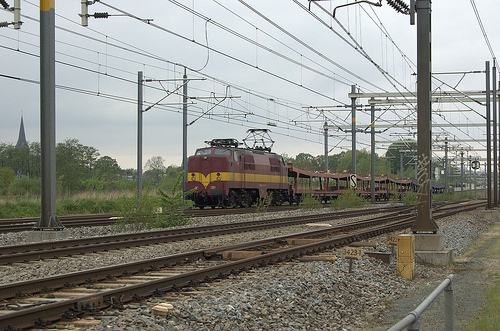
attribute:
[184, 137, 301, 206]
car — maroon, yellow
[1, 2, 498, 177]
sky — grey, cloudy, background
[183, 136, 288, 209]
train engine — red, yellow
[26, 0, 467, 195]
poles — beside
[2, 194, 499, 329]
tracks — steel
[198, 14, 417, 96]
wires — above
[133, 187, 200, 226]
bushes — small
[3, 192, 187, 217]
grass — beside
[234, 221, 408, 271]
pieces — wood